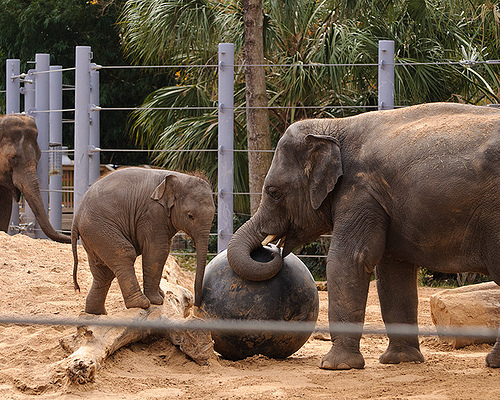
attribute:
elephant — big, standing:
[226, 101, 499, 369]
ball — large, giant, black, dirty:
[202, 245, 320, 360]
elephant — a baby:
[72, 167, 215, 314]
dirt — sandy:
[3, 227, 499, 399]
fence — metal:
[1, 40, 499, 258]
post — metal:
[217, 42, 233, 253]